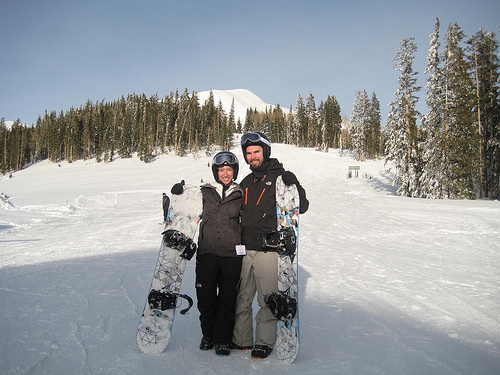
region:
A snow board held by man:
[282, 187, 294, 357]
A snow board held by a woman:
[170, 212, 187, 258]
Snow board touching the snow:
[141, 342, 161, 351]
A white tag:
[236, 246, 245, 254]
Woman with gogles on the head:
[218, 154, 231, 161]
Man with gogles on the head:
[242, 135, 258, 140]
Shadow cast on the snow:
[16, 304, 58, 346]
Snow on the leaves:
[392, 137, 404, 160]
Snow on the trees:
[412, 141, 441, 196]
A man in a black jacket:
[236, 127, 308, 361]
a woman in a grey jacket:
[166, 149, 251, 357]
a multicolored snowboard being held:
[258, 173, 299, 363]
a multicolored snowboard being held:
[133, 180, 203, 352]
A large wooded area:
[0, 15, 498, 200]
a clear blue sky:
[0, 2, 498, 126]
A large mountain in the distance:
[173, 85, 295, 130]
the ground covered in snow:
[0, 130, 499, 372]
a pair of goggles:
[237, 132, 272, 149]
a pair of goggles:
[211, 151, 241, 168]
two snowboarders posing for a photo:
[137, 129, 307, 356]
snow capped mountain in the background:
[186, 86, 296, 128]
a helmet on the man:
[241, 128, 271, 170]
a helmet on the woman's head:
[212, 150, 239, 182]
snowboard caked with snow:
[136, 183, 201, 356]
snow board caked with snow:
[275, 175, 297, 364]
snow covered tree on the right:
[383, 34, 425, 195]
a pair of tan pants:
[233, 247, 281, 344]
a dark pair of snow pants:
[196, 250, 240, 342]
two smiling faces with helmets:
[212, 125, 277, 191]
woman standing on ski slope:
[195, 153, 241, 351]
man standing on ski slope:
[236, 130, 305, 342]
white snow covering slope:
[52, 157, 487, 372]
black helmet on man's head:
[241, 125, 275, 157]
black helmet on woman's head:
[216, 149, 245, 181]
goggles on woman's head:
[217, 150, 243, 164]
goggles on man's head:
[227, 123, 272, 148]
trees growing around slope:
[32, 100, 383, 151]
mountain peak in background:
[206, 75, 250, 131]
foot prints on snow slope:
[348, 250, 494, 371]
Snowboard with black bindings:
[127, 180, 202, 353]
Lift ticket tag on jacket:
[230, 240, 245, 255]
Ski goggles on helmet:
[207, 150, 237, 162]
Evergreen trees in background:
[2, 30, 492, 190]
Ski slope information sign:
[345, 160, 360, 175]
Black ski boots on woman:
[195, 335, 230, 355]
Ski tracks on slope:
[310, 197, 490, 362]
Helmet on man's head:
[241, 130, 272, 163]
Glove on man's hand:
[281, 169, 296, 189]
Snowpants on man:
[228, 249, 281, 347]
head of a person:
[240, 132, 266, 164]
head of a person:
[211, 150, 232, 181]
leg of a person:
[255, 262, 281, 346]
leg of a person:
[230, 259, 254, 349]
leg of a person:
[215, 261, 242, 350]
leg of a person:
[196, 254, 216, 341]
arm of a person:
[279, 170, 309, 215]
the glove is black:
[170, 179, 187, 194]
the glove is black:
[281, 170, 295, 183]